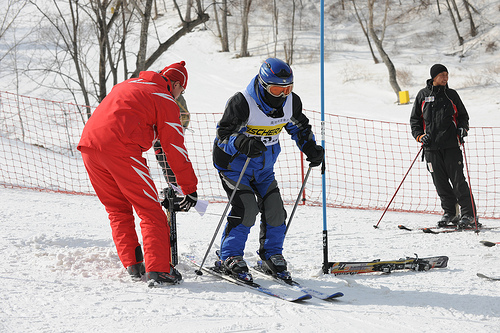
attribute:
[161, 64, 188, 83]
hat — red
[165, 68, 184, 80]
stripe — white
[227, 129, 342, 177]
gloves — black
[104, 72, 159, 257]
suit — red 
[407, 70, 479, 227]
man — bent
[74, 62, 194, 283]
man — leaning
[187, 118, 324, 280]
poles — ski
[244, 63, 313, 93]
helmet — blue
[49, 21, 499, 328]
people — skiing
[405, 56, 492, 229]
man — smiling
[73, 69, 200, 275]
suit — orange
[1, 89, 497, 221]
net — Red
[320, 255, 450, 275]
ski — lone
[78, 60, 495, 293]
men — winter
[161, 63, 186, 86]
hat — red, white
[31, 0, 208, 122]
tree — bare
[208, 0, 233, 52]
tree — bare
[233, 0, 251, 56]
tree — bare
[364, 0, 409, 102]
tree — bare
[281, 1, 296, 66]
tree — bare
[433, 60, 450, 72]
cap — black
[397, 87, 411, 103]
object — yellow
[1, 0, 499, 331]
snow — covering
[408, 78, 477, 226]
clothing — black, winter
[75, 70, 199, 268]
outfit — red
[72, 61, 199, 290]
gear — orange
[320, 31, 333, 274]
pole — blue, tall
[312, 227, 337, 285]
base — black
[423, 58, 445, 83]
hat — black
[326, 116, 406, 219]
net — red, mesh